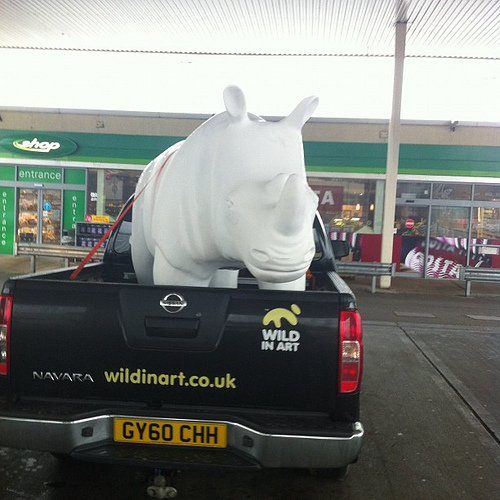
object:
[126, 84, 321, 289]
rhino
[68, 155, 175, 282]
strap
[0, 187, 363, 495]
truck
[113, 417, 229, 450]
license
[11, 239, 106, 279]
railing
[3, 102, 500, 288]
store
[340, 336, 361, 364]
tail light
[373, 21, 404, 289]
post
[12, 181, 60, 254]
door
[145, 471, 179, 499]
hitch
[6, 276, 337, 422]
tail gate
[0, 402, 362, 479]
bumper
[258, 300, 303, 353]
logo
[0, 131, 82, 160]
sign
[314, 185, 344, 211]
poster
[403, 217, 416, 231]
caution sign